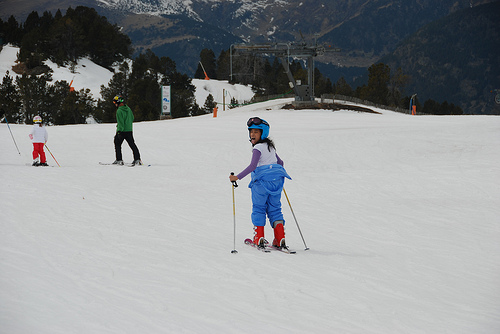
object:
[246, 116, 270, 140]
hat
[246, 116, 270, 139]
head gear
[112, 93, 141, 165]
guy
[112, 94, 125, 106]
hat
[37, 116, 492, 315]
field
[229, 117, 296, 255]
female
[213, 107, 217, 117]
pole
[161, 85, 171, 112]
sign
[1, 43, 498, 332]
snow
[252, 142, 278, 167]
vest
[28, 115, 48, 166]
kid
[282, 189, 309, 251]
snow stick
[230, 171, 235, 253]
snow stick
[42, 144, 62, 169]
snow stick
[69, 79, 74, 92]
flag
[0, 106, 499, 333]
ski slope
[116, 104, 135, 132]
green jacket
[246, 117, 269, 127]
goggles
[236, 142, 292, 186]
top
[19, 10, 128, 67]
trees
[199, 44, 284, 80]
trees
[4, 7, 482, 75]
mountain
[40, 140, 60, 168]
stick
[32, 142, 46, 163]
red pants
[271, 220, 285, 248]
shoe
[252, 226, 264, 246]
shoe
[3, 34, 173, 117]
hill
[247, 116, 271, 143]
head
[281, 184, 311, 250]
pole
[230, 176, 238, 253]
pole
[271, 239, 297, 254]
ski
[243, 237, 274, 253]
ski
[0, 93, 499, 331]
ground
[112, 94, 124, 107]
helmet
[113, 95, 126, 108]
head